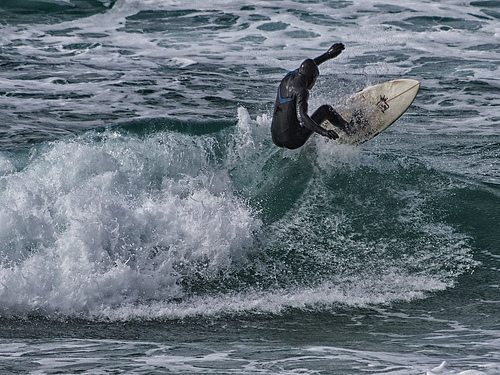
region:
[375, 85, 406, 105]
A surf board out of the water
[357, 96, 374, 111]
Water splashing down a board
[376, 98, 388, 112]
A black mark on a surf board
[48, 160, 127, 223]
Foam from a wave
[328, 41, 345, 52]
A hand held out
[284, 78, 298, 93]
A wet suit glistening in the light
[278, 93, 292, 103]
A blue mark on the wet suit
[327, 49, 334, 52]
Light reflected by hand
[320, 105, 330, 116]
Surfer's knee above the waist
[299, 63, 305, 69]
A spot of light reflected by the head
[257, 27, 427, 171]
man surfing in the ocean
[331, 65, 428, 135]
surfboard in the ocean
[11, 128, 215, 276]
water splashing from the waves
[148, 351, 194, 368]
white foam on ocean water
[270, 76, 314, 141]
black wetsuit on a surfer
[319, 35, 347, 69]
left arm of a surfer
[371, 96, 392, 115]
design on a surfboard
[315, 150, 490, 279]
wave in the ocean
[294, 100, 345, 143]
right arm of a surfer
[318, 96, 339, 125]
right knee of a surfer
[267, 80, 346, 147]
Black surfing wear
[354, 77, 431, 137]
A white surf board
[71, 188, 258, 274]
Violent waves in the photo.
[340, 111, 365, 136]
Black shoes in the photo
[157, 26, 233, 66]
White sea waters in the photo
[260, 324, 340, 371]
Calm ocean waters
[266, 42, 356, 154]
A person surfing in the waters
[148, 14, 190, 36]
Blue waters of the sea.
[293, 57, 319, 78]
A hat on the head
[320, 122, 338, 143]
Black gloves on the hand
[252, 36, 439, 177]
Man on a surfboard.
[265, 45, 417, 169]
Man in a wetsuit.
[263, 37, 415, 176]
Man in a black wet suit.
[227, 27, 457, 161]
Surfboard on the water.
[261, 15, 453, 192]
Man surfing in the water.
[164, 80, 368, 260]
Spray from the ocean.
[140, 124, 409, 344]
Waves on the ocean.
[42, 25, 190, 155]
Ripples on the ocean.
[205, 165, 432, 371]
White foam on the ocean.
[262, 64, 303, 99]
Blue stripe on the wet suit.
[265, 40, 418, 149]
A person surfing on a wave.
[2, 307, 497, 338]
Water droplets hitting the water.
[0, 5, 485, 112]
White foam on the water's surface.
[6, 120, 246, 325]
A crashing wave.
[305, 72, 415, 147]
Water spray around the surboard.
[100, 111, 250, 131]
A rolling wave on the water.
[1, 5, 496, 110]
The water is choppy.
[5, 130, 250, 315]
White water on the wave.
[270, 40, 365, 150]
A surfer wearing a black wetsuit.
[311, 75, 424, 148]
A white surfboard with black lettering.